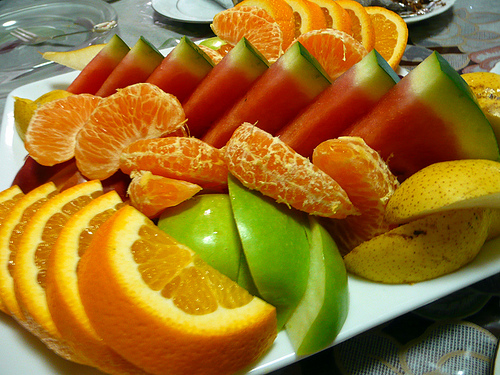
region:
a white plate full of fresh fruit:
[0, 1, 498, 373]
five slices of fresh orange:
[1, 178, 277, 373]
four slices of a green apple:
[151, 170, 346, 360]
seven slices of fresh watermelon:
[12, 35, 498, 192]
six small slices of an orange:
[25, 83, 394, 250]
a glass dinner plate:
[0, 3, 119, 80]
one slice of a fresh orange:
[75, 203, 275, 373]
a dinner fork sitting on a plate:
[1, 2, 120, 77]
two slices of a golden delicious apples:
[345, 161, 498, 281]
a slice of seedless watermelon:
[348, 53, 498, 178]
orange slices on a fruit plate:
[16, 162, 283, 357]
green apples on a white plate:
[170, 188, 396, 353]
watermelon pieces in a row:
[74, 0, 493, 177]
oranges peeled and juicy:
[27, 92, 417, 234]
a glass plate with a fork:
[15, 23, 80, 65]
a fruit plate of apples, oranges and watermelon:
[44, 34, 411, 296]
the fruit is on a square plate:
[16, 30, 490, 332]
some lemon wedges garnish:
[340, 175, 493, 274]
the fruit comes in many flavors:
[11, 40, 460, 268]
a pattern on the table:
[423, 33, 496, 76]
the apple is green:
[261, 218, 280, 250]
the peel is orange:
[95, 283, 116, 305]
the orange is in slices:
[120, 218, 232, 335]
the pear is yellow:
[413, 182, 435, 201]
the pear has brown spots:
[438, 228, 464, 250]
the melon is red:
[379, 121, 401, 140]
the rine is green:
[441, 64, 460, 81]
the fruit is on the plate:
[242, 281, 376, 343]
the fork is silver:
[10, 25, 66, 47]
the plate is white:
[357, 284, 397, 311]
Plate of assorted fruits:
[1, 0, 498, 371]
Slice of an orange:
[78, 203, 277, 373]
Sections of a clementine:
[25, 86, 396, 217]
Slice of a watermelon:
[339, 52, 496, 176]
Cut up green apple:
[160, 181, 347, 356]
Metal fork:
[9, 14, 115, 49]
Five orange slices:
[0, 178, 280, 370]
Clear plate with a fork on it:
[0, 0, 117, 79]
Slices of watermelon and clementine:
[81, 35, 498, 180]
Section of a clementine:
[224, 122, 353, 219]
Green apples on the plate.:
[203, 193, 323, 322]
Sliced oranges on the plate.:
[30, 195, 176, 332]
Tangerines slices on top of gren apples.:
[54, 92, 184, 188]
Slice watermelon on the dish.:
[175, 54, 429, 176]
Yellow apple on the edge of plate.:
[406, 171, 496, 252]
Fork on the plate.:
[8, 10, 146, 55]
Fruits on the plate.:
[58, 38, 445, 293]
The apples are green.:
[189, 217, 371, 324]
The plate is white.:
[328, 267, 450, 334]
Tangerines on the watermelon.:
[51, 74, 163, 173]